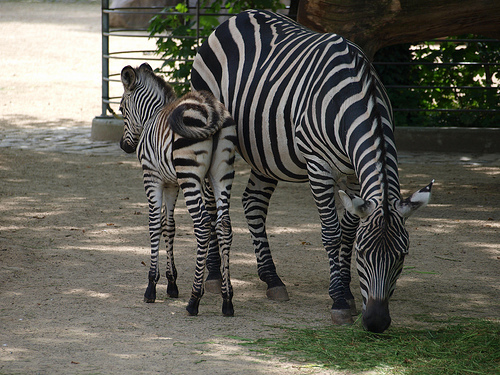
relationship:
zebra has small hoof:
[104, 62, 232, 324] [220, 289, 235, 318]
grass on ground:
[253, 319, 499, 374] [4, 107, 498, 367]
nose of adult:
[362, 298, 392, 338] [189, 9, 435, 333]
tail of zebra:
[161, 87, 232, 162] [117, 59, 238, 319]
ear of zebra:
[393, 178, 437, 230] [172, 3, 438, 346]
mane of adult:
[356, 50, 392, 214] [189, 9, 435, 333]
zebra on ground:
[104, 62, 232, 324] [0, 2, 500, 372]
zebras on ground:
[186, 5, 436, 331] [0, 2, 500, 372]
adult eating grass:
[189, 9, 435, 333] [253, 319, 499, 374]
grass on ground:
[253, 319, 499, 374] [0, 2, 500, 372]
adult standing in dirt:
[189, 9, 435, 333] [0, 115, 500, 373]